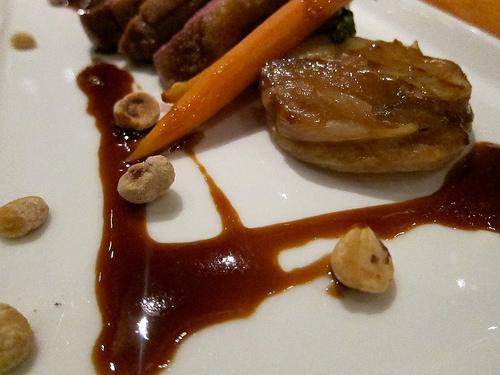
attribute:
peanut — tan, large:
[117, 153, 176, 204]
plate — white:
[1, 0, 499, 373]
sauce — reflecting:
[76, 57, 498, 373]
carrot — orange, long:
[123, 0, 353, 164]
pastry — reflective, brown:
[259, 35, 476, 174]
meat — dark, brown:
[152, 0, 292, 91]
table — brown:
[418, 0, 499, 39]